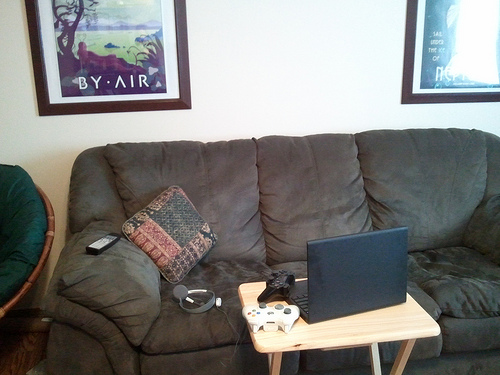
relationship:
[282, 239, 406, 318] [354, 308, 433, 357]
laptop on table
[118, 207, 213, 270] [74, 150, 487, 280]
pillow on couch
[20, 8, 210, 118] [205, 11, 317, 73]
painting on wall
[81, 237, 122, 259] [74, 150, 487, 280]
remote control on couch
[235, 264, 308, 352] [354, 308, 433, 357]
controllers on table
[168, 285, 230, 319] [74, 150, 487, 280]
headphones on couch